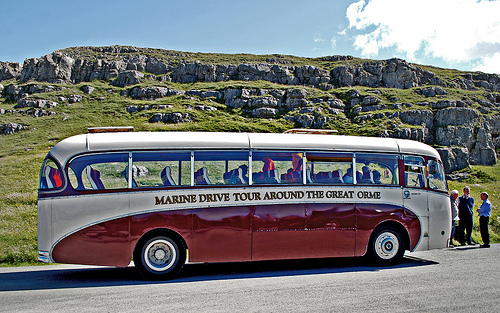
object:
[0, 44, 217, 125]
hills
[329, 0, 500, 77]
clouds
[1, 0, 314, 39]
sky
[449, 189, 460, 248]
people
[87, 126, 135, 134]
roof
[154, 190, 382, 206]
text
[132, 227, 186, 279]
tire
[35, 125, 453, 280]
bus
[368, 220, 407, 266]
tire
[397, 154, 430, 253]
bus door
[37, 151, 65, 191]
window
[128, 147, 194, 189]
window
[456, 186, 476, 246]
man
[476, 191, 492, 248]
men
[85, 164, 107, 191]
seats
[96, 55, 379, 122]
landscape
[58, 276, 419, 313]
road